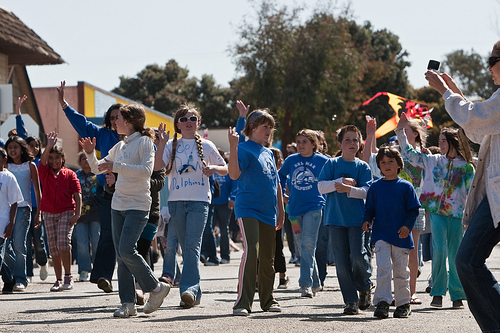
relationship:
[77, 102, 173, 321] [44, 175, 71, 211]
child wearing shirt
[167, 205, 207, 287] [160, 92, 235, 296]
jeans on girl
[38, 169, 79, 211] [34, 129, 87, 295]
shirt on girl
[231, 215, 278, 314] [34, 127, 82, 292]
pants on girl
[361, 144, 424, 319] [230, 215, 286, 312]
boy wears pants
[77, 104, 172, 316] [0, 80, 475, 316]
child in parade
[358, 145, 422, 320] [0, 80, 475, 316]
boy in parade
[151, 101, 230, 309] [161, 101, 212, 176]
girl has hair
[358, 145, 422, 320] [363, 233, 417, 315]
boy wearing white pants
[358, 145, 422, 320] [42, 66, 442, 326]
boy walking in parade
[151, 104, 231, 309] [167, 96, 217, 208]
girl has pigtails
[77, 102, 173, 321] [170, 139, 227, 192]
child wearing shirt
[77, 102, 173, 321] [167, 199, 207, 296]
child wearing blue pants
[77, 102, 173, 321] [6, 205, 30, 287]
child wearing blue pants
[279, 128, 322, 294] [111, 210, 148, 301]
girl wearing blue pants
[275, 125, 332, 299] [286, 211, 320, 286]
girl wearing blue pants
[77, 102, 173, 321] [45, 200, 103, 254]
child wearing pants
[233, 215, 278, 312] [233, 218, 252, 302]
pants have stripe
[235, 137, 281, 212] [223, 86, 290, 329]
shirt on girl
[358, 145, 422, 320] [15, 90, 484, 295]
boy in parade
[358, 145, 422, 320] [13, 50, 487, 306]
boy walking in parade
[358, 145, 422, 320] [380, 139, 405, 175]
boy has hair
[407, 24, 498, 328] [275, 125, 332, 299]
woman taking picture of girl